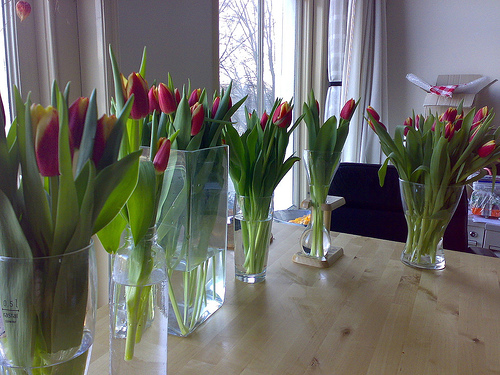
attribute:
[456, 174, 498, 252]
cabinet — silver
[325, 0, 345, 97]
drape — plaid